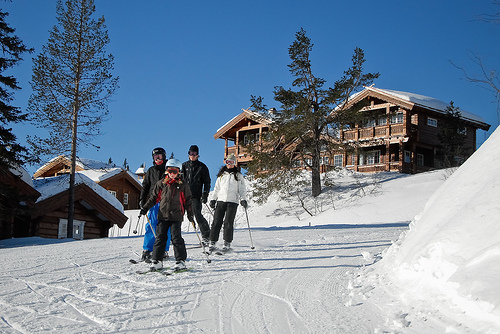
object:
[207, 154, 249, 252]
skier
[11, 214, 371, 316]
slope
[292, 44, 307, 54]
leaves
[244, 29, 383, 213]
tree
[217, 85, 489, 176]
building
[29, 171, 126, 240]
building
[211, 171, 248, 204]
jacket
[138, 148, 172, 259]
skier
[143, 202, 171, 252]
pants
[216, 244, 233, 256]
skies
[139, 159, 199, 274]
skier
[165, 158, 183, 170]
helmet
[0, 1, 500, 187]
sky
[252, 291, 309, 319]
tracks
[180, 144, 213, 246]
skier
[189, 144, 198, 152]
cap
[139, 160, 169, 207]
jacket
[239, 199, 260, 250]
ski pole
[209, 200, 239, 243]
pants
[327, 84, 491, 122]
roof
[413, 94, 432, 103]
snow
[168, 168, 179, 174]
goggles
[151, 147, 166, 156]
helmet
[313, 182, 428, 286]
snow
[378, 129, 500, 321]
hillside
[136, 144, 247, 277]
people